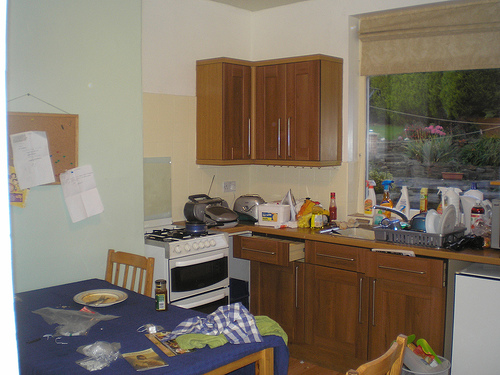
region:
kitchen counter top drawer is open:
[231, 227, 307, 269]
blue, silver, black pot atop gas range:
[183, 217, 227, 235]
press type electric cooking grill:
[203, 203, 240, 228]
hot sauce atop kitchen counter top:
[328, 189, 337, 226]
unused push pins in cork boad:
[51, 145, 74, 167]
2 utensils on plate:
[76, 287, 128, 307]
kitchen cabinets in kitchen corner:
[186, 32, 348, 169]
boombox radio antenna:
[203, 171, 219, 202]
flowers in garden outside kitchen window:
[393, 119, 452, 144]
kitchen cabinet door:
[298, 259, 365, 366]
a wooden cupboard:
[253, 252, 302, 344]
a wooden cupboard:
[234, 235, 294, 270]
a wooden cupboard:
[301, 229, 364, 269]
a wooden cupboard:
[310, 262, 362, 367]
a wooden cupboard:
[372, 248, 442, 292]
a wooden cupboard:
[367, 279, 439, 364]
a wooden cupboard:
[218, 61, 254, 166]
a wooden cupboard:
[251, 60, 291, 150]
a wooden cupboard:
[286, 65, 318, 157]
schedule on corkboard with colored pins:
[5, 110, 105, 226]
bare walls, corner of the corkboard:
[55, 24, 198, 145]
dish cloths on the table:
[173, 283, 273, 350]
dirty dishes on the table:
[30, 277, 165, 363]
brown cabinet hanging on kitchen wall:
[190, 57, 333, 180]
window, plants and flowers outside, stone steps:
[343, 42, 489, 178]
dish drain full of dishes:
[360, 185, 490, 277]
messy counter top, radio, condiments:
[156, 177, 327, 245]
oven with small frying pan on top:
[150, 205, 230, 281]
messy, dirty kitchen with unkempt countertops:
[25, 50, 460, 362]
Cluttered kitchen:
[19, 12, 489, 358]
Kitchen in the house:
[16, 7, 497, 353]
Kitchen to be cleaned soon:
[145, 0, 495, 265]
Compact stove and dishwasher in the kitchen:
[142, 5, 487, 372]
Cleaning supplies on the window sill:
[353, 15, 494, 266]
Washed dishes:
[377, 190, 497, 271]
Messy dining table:
[22, 225, 282, 362]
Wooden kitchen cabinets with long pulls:
[147, 50, 492, 358]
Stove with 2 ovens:
[140, 190, 256, 325]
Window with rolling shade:
[338, 2, 499, 256]